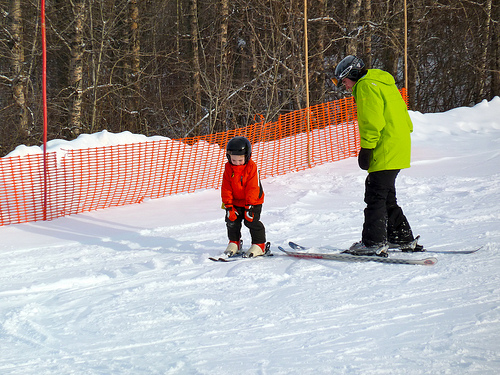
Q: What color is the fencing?
A: Orange.